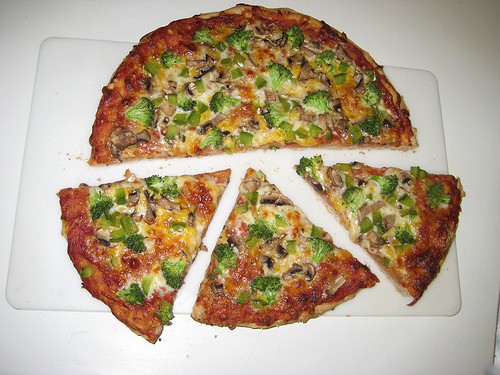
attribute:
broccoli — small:
[300, 156, 320, 178]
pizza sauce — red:
[234, 253, 264, 280]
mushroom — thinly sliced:
[306, 262, 316, 281]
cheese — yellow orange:
[148, 215, 177, 251]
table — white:
[0, 1, 499, 374]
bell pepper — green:
[186, 112, 202, 129]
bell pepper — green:
[167, 93, 180, 106]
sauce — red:
[113, 99, 130, 129]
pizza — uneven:
[54, 166, 230, 343]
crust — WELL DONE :
[437, 169, 460, 261]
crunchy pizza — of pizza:
[57, 185, 97, 260]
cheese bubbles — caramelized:
[232, 65, 258, 119]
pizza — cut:
[90, 10, 452, 327]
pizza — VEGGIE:
[58, 5, 465, 347]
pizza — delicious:
[119, 13, 399, 142]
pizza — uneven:
[75, 4, 407, 168]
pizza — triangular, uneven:
[190, 167, 380, 329]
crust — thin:
[191, 168, 378, 326]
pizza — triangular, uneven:
[299, 157, 459, 304]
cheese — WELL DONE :
[91, 172, 221, 301]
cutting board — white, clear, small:
[5, 34, 462, 319]